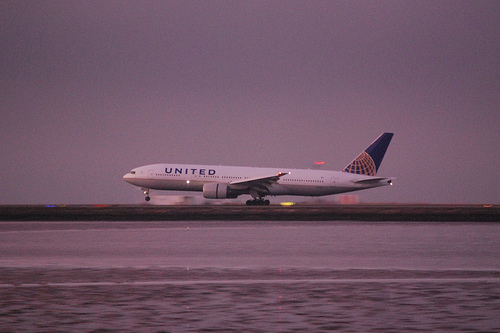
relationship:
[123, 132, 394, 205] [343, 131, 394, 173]
airplane has tail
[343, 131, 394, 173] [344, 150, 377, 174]
tail has design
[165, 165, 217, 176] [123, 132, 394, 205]
writing on surface of airplane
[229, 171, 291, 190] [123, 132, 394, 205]
wing attached to airplane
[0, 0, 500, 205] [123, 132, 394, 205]
sky behind airplane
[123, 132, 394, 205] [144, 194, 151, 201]
airplane has front wheels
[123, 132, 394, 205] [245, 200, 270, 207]
airplane has back wheels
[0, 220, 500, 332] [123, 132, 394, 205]
water in front of airplane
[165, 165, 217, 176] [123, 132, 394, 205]
writing on airplane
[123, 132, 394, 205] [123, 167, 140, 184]
airplane has nose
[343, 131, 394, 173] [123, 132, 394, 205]
tail attached to airplane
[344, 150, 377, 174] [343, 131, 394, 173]
design printed on tail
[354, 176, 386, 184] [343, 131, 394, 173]
wing next to tail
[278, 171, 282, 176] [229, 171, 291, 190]
light mounted on wing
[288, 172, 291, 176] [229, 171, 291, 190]
light mounted on wing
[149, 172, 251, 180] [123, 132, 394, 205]
passenger windows on side of airplane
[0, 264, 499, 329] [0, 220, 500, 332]
ripples on surface of water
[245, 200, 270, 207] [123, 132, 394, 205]
back wheels attached to airplane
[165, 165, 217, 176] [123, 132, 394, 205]
writing on side of airplane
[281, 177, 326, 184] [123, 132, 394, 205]
passenger windows inside airplane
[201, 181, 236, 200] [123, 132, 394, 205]
side engine attached to airplane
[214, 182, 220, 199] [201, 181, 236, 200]
stripe painted on engine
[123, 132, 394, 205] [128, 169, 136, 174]
airplane has windshield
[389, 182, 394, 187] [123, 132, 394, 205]
light mounted on airplane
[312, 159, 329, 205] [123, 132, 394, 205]
tower behind airplane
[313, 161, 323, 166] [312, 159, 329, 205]
lights on tower